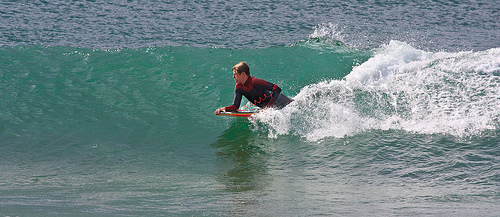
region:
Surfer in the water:
[211, 60, 314, 124]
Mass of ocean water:
[0, 0, 198, 205]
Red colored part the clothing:
[233, 82, 257, 93]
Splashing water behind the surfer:
[299, 66, 480, 145]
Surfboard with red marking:
[215, 109, 267, 118]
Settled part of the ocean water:
[1, 1, 473, 36]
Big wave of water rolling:
[5, 37, 230, 157]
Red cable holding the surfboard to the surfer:
[242, 91, 278, 109]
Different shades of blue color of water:
[4, 13, 152, 98]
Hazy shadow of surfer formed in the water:
[190, 112, 282, 196]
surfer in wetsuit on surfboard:
[202, 50, 287, 140]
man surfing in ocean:
[194, 31, 344, 157]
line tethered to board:
[230, 83, 281, 146]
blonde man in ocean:
[222, 56, 312, 149]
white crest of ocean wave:
[321, 44, 483, 151]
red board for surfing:
[232, 97, 309, 139]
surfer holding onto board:
[182, 98, 286, 128]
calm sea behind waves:
[25, 9, 114, 39]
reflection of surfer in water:
[185, 127, 270, 196]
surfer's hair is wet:
[226, 58, 251, 96]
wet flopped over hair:
[228, 55, 253, 80]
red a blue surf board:
[217, 104, 274, 125]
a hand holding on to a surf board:
[216, 103, 233, 118]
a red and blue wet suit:
[228, 76, 301, 111]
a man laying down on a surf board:
[179, 52, 335, 145]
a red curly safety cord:
[222, 77, 287, 119]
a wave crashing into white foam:
[292, 43, 498, 146]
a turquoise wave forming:
[17, 41, 197, 123]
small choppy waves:
[157, 8, 279, 35]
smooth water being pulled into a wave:
[50, 173, 279, 209]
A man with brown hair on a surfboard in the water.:
[213, 61, 293, 115]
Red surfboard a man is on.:
[213, 107, 254, 119]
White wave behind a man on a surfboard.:
[251, 35, 498, 140]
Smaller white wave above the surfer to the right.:
[306, 24, 355, 48]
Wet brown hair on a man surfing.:
[228, 59, 250, 76]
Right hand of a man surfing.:
[208, 103, 224, 113]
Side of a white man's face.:
[232, 67, 242, 84]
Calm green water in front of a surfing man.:
[132, 82, 211, 137]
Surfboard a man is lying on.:
[215, 107, 269, 117]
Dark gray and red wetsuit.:
[218, 71, 300, 111]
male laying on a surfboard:
[209, 55, 301, 127]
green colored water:
[10, 46, 212, 172]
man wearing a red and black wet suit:
[213, 61, 305, 115]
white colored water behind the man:
[256, 41, 499, 144]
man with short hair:
[221, 57, 258, 85]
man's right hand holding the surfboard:
[211, 99, 243, 119]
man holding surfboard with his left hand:
[258, 79, 271, 124]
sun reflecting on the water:
[19, 161, 470, 203]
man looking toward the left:
[218, 60, 299, 133]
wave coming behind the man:
[0, 40, 352, 80]